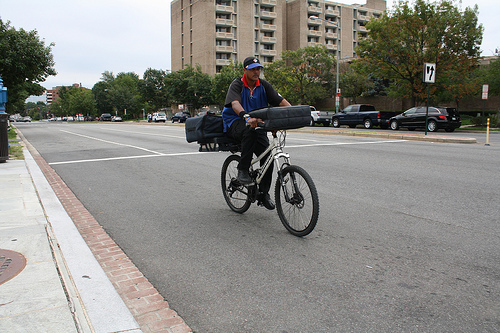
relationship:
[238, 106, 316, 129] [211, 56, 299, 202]
pizza delivery man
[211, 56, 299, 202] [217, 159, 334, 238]
man on bicycle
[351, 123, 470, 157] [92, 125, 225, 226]
raised median in street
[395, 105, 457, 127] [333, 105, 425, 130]
dark colored truck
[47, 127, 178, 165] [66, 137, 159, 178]
lines on pavement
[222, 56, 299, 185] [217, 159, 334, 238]
man riding bike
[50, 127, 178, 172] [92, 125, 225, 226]
lines on street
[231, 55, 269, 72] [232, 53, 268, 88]
hat on head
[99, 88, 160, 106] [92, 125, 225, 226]
trees next to street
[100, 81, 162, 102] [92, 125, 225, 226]
green tree next to street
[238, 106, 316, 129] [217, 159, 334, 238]
black delivery case on bike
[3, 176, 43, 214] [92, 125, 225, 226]
gray sidewalk next to street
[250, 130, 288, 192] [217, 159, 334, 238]
white bike with black wheels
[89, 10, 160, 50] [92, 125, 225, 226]
white sky above street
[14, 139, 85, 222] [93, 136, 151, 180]
edge of a road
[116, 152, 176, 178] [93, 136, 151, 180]
part of a floor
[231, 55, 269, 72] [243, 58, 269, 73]
black red white baseball cap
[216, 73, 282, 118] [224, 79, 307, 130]
black red white work shirt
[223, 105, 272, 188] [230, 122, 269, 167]
pair of black pants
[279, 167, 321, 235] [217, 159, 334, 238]
black wheel of bike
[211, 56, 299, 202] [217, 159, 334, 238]
man riding a bike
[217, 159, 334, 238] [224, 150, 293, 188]
bike colored silver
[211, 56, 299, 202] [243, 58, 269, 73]
man wearing cap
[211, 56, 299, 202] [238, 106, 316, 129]
man carrying a pizza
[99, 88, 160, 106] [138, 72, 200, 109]
trees are in background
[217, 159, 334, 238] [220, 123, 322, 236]
wheels on bike